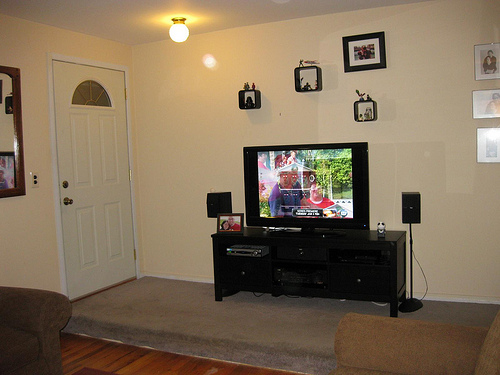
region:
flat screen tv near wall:
[219, 116, 371, 235]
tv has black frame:
[233, 129, 413, 271]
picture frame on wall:
[340, 35, 395, 77]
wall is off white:
[134, 109, 204, 197]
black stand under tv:
[215, 229, 420, 311]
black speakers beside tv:
[186, 176, 429, 220]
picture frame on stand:
[204, 200, 249, 244]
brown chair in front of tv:
[312, 276, 457, 373]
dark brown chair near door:
[1, 285, 112, 362]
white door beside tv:
[48, 69, 154, 271]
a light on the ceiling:
[160, 13, 195, 47]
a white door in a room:
[39, 49, 151, 304]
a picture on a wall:
[335, 26, 386, 75]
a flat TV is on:
[238, 135, 375, 231]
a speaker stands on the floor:
[397, 185, 427, 320]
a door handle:
[58, 191, 75, 211]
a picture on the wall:
[469, 35, 499, 81]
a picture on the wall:
[465, 84, 499, 118]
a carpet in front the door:
[61, 262, 491, 374]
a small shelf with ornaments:
[345, 86, 384, 126]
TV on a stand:
[235, 136, 381, 236]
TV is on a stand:
[235, 140, 380, 237]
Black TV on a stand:
[240, 140, 375, 240]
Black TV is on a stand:
[235, 137, 375, 238]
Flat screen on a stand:
[235, 138, 375, 234]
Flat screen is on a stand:
[234, 138, 383, 240]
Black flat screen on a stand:
[237, 140, 377, 239]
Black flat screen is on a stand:
[238, 139, 388, 240]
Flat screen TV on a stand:
[239, 138, 377, 242]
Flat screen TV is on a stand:
[236, 140, 375, 240]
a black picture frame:
[338, 27, 390, 75]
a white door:
[51, 54, 148, 298]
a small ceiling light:
[165, 15, 193, 47]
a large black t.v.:
[237, 143, 372, 219]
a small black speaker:
[399, 188, 426, 225]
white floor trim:
[407, 288, 499, 307]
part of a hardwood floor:
[45, 333, 302, 373]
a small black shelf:
[236, 86, 266, 113]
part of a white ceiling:
[3, 0, 158, 46]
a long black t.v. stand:
[208, 225, 408, 309]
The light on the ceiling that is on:
[157, 16, 192, 43]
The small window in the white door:
[65, 81, 117, 111]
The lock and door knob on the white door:
[59, 177, 75, 212]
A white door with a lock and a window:
[44, 53, 139, 298]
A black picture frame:
[338, 30, 389, 70]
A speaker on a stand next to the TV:
[397, 184, 428, 315]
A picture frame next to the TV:
[210, 211, 247, 233]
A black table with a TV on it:
[217, 225, 402, 320]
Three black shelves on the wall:
[221, 60, 383, 138]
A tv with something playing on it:
[235, 143, 375, 236]